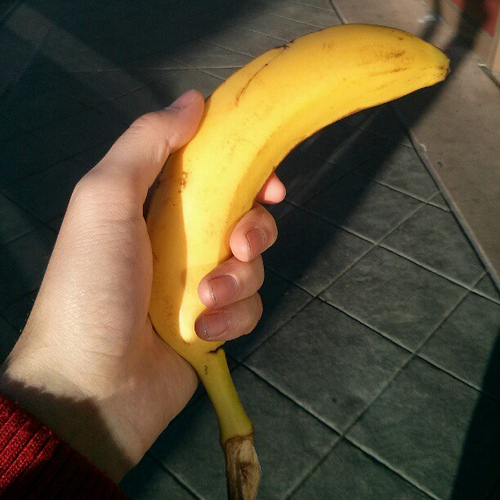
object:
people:
[0, 90, 291, 497]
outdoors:
[0, 0, 264, 63]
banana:
[141, 24, 449, 499]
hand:
[6, 96, 285, 469]